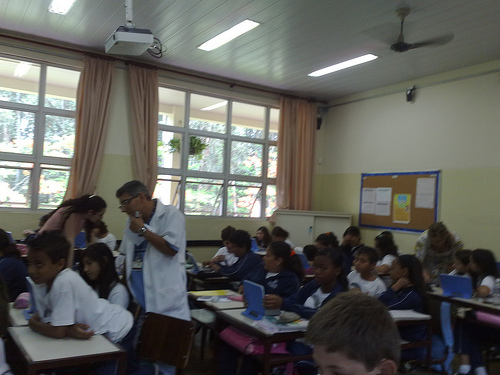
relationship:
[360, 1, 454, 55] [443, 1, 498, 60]
fan hanging from ceiling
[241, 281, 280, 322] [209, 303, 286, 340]
computer on desktop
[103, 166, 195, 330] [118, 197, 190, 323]
man in jacket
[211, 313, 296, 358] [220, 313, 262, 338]
desktop with frame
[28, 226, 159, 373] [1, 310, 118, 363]
boy on desktop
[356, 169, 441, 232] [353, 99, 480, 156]
board hanging on wall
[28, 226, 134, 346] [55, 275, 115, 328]
boy wearing shirt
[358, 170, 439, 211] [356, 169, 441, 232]
papers on board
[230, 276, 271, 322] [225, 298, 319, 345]
computer on table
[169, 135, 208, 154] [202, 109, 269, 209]
plant outside window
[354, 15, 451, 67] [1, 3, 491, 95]
fan hung from ceiling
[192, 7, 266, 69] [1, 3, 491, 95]
light built into ceiling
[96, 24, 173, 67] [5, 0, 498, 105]
projector hanging from ceiling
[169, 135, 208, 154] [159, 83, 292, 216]
plant outside window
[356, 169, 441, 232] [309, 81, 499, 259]
board on wall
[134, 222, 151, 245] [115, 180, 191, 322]
wristwatch worn by man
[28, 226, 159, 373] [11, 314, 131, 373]
boy leaning on desk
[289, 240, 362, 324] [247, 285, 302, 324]
student using computer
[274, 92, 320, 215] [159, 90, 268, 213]
drapes on window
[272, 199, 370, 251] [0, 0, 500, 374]
cabinet in corner of classroom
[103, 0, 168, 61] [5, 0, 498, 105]
projector hanging from ceiling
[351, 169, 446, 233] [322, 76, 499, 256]
board on wall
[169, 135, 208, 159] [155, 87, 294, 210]
plant hanging outside window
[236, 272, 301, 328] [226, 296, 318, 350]
screen on desk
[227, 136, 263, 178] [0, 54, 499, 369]
pane in classroom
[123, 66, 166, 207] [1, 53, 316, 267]
curtain on wall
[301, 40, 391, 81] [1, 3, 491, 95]
light on ceiling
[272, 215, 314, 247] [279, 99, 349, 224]
cabinet in corner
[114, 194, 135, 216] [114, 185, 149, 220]
glasses on face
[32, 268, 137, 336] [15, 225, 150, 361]
shirt on boy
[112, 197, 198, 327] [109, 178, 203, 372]
jacket on man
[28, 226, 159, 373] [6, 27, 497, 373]
boy in class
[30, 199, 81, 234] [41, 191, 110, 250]
shirt on woman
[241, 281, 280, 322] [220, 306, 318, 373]
computer on table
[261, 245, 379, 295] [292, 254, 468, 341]
boys at desks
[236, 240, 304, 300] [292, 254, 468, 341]
student at desks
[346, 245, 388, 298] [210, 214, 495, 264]
boys has hair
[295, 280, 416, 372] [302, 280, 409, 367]
child has hair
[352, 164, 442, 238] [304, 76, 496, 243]
bullitin board on wall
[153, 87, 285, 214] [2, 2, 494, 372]
windows in classroom